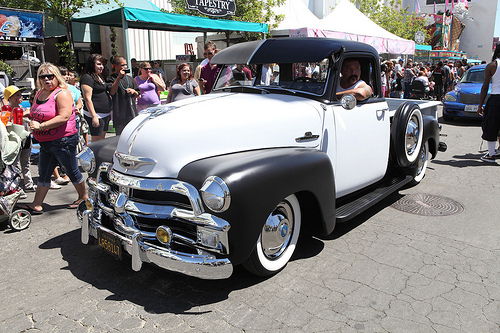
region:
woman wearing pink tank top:
[18, 60, 88, 213]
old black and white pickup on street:
[76, 35, 448, 285]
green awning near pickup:
[44, 0, 270, 35]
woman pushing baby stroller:
[1, 113, 38, 235]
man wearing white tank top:
[476, 37, 499, 167]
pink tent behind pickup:
[291, 0, 413, 56]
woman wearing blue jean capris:
[32, 133, 89, 184]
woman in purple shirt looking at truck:
[132, 60, 164, 108]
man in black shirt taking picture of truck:
[103, 54, 140, 130]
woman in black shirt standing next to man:
[77, 51, 112, 143]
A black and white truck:
[50, 16, 460, 302]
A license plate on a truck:
[85, 217, 133, 272]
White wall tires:
[212, 167, 339, 302]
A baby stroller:
[2, 114, 43, 237]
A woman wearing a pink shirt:
[8, 51, 105, 228]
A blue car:
[420, 52, 495, 139]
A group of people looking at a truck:
[2, 15, 293, 227]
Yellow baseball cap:
[0, 78, 34, 108]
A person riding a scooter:
[400, 64, 447, 106]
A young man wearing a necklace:
[95, 51, 148, 136]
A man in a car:
[329, 56, 377, 93]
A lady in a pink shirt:
[31, 52, 84, 214]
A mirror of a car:
[332, 91, 360, 114]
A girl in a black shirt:
[80, 49, 112, 130]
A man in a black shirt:
[107, 52, 136, 116]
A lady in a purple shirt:
[133, 53, 158, 103]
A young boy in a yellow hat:
[0, 80, 26, 119]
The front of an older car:
[77, 112, 340, 287]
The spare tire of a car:
[391, 93, 423, 179]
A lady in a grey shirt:
[166, 55, 199, 95]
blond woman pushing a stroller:
[0, 58, 89, 233]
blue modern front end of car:
[443, 65, 498, 124]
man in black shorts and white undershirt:
[477, 34, 499, 164]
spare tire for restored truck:
[389, 102, 426, 167]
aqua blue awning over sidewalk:
[75, 3, 269, 34]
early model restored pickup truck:
[72, 33, 442, 282]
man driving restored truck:
[334, 55, 375, 100]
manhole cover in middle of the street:
[394, 187, 469, 221]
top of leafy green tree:
[354, 0, 426, 38]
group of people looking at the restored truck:
[83, 38, 219, 120]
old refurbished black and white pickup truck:
[76, 36, 447, 278]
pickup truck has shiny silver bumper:
[76, 199, 231, 281]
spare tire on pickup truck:
[390, 101, 424, 166]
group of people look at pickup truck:
[58, 52, 201, 143]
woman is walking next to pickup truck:
[16, 61, 88, 215]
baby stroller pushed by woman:
[0, 115, 40, 230]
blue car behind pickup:
[441, 63, 498, 124]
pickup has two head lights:
[75, 146, 230, 213]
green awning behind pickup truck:
[47, 0, 269, 77]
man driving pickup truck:
[334, 57, 372, 102]